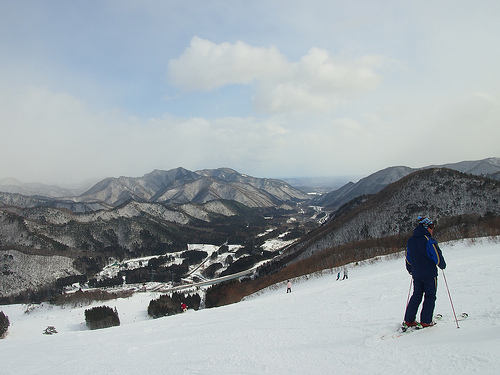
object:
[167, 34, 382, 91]
cloud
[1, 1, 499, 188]
sky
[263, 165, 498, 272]
hill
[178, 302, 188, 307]
jacket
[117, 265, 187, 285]
tree cluster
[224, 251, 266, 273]
tree cluster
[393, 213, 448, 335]
skier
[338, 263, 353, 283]
skier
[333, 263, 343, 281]
skier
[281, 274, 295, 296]
skier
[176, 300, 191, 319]
skier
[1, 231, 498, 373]
slope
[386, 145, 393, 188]
ground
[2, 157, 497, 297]
mountains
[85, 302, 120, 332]
trees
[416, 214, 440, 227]
hat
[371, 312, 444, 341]
skis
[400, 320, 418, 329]
boot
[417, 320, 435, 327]
boot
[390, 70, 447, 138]
ground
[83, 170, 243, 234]
hill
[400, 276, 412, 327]
ski pole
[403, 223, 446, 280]
jacket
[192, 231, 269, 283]
trees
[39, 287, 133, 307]
trees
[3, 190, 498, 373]
snow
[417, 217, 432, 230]
knit cap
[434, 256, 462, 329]
pole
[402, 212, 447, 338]
person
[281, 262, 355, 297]
people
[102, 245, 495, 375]
hill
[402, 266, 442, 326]
pants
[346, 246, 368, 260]
trees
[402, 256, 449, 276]
hand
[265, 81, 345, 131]
cloud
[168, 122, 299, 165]
cloud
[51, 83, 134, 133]
cloud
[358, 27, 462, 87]
cloud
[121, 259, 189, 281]
tree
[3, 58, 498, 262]
distance